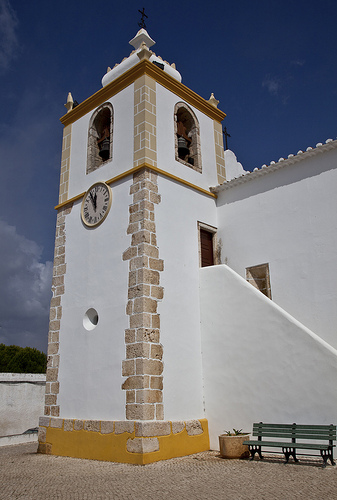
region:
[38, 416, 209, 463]
yellow foundation of the tower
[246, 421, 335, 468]
empty green bench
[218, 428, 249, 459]
planter with small plants next to a bench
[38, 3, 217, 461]
brick and stucco tower on a church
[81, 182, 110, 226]
large clock on the side of the tower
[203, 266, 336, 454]
stairway leading up to the tower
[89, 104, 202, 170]
two windows with bells at the tower's top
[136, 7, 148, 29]
black cross on top of the tower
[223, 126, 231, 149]
cross to the right of the tower on the roof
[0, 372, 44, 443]
wall behind the tower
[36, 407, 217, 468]
brick and orange corner wall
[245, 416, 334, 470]
forest green wood bench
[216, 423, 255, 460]
large stone plant pot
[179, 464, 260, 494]
exterior brick beige grown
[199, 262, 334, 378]
white rail wall stairs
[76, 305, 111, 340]
circular thick white window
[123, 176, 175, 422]
brick cover corner wall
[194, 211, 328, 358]
wood door on top of staircase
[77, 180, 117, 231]
beige and black large clock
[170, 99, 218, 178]
large steel church bell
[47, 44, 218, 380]
White church tower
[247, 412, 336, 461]
Small green park bench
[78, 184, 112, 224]
Clock face on building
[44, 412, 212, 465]
Lower yellow border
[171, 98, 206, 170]
Bell in window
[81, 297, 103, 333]
Small circular hole in wall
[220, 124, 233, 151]
Metal cross in background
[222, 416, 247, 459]
Potted plant beside bench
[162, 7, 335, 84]
Blue sky is bright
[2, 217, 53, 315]
White cloud in background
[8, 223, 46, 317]
large section of white clouds in the sky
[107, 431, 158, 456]
bricks on yellow wall base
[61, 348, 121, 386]
white paint on wall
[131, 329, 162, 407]
red bricks at wall's edge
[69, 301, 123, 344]
round hole in wall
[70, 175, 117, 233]
gold clock on wall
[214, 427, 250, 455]
brown concrete pot on ground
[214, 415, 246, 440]
green plant in pot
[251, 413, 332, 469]
green bench on ground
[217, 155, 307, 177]
white scalloped edge on roof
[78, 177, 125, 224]
A clock on a building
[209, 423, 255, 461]
A planter next to a bench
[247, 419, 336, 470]
A green wooden bench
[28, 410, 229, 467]
Yellow trim on bottom of building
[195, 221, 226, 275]
A door at the top of the stairs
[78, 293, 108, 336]
A round hole below clock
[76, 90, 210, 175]
Two openings at the top of building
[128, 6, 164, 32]
A black cross on top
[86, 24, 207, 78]
White steeple topped with black cross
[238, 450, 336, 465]
Shadow cast on ground from bench